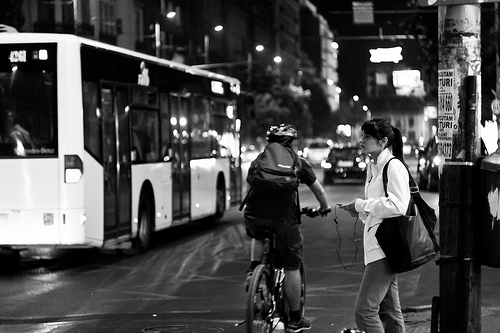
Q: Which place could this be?
A: It is a street.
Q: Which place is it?
A: It is a street.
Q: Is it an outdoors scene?
A: Yes, it is outdoors.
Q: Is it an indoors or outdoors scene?
A: It is outdoors.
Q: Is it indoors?
A: No, it is outdoors.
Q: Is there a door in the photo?
A: Yes, there is a door.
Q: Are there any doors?
A: Yes, there is a door.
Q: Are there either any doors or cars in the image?
A: Yes, there is a door.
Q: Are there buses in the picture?
A: Yes, there is a bus.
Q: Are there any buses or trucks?
A: Yes, there is a bus.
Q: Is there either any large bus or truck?
A: Yes, there is a large bus.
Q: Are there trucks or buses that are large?
A: Yes, the bus is large.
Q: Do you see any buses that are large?
A: Yes, there is a large bus.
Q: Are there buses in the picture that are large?
A: Yes, there is a bus that is large.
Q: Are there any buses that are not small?
A: Yes, there is a large bus.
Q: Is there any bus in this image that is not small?
A: Yes, there is a large bus.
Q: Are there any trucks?
A: No, there are no trucks.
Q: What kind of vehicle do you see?
A: The vehicle is a bus.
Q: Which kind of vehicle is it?
A: The vehicle is a bus.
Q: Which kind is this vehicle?
A: This is a bus.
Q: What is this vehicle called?
A: This is a bus.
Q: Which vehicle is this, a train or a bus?
A: This is a bus.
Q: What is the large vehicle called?
A: The vehicle is a bus.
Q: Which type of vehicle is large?
A: The vehicle is a bus.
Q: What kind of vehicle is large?
A: The vehicle is a bus.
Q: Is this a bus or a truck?
A: This is a bus.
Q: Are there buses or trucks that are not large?
A: No, there is a bus but it is large.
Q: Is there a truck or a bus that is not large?
A: No, there is a bus but it is large.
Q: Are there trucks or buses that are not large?
A: No, there is a bus but it is large.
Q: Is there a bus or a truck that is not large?
A: No, there is a bus but it is large.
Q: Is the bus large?
A: Yes, the bus is large.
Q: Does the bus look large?
A: Yes, the bus is large.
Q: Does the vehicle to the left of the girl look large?
A: Yes, the bus is large.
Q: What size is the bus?
A: The bus is large.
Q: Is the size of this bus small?
A: No, the bus is large.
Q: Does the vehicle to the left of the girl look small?
A: No, the bus is large.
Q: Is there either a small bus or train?
A: No, there is a bus but it is large.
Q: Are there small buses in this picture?
A: No, there is a bus but it is large.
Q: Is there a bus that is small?
A: No, there is a bus but it is large.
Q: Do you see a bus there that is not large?
A: No, there is a bus but it is large.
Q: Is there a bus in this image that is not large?
A: No, there is a bus but it is large.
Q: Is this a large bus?
A: Yes, this is a large bus.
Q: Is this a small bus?
A: No, this is a large bus.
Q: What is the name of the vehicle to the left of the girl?
A: The vehicle is a bus.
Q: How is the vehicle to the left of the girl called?
A: The vehicle is a bus.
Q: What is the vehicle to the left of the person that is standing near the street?
A: The vehicle is a bus.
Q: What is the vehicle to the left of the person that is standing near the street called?
A: The vehicle is a bus.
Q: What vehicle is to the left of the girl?
A: The vehicle is a bus.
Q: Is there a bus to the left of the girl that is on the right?
A: Yes, there is a bus to the left of the girl.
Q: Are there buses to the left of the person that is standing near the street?
A: Yes, there is a bus to the left of the girl.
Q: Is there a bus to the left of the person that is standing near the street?
A: Yes, there is a bus to the left of the girl.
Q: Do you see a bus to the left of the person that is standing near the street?
A: Yes, there is a bus to the left of the girl.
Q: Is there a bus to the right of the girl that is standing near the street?
A: No, the bus is to the left of the girl.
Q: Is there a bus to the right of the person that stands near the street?
A: No, the bus is to the left of the girl.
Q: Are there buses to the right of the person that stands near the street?
A: No, the bus is to the left of the girl.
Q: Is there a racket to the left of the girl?
A: No, there is a bus to the left of the girl.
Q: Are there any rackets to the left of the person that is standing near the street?
A: No, there is a bus to the left of the girl.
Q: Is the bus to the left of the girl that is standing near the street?
A: Yes, the bus is to the left of the girl.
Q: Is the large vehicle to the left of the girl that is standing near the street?
A: Yes, the bus is to the left of the girl.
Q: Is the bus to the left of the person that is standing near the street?
A: Yes, the bus is to the left of the girl.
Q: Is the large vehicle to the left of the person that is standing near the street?
A: Yes, the bus is to the left of the girl.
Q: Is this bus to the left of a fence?
A: No, the bus is to the left of the girl.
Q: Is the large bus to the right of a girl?
A: No, the bus is to the left of a girl.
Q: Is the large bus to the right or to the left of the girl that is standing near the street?
A: The bus is to the left of the girl.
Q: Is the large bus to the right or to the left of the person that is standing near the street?
A: The bus is to the left of the girl.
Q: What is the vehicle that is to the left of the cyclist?
A: The vehicle is a bus.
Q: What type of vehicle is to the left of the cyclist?
A: The vehicle is a bus.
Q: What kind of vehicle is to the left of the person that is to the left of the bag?
A: The vehicle is a bus.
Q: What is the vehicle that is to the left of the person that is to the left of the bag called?
A: The vehicle is a bus.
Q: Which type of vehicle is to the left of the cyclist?
A: The vehicle is a bus.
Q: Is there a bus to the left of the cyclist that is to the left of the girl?
A: Yes, there is a bus to the left of the bicyclist.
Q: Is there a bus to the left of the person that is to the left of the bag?
A: Yes, there is a bus to the left of the bicyclist.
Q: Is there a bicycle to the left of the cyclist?
A: No, there is a bus to the left of the cyclist.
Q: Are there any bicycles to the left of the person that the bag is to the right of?
A: No, there is a bus to the left of the cyclist.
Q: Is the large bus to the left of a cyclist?
A: Yes, the bus is to the left of a cyclist.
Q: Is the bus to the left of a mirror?
A: No, the bus is to the left of a cyclist.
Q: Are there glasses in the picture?
A: No, there are no glasses.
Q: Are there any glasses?
A: No, there are no glasses.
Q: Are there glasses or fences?
A: No, there are no glasses or fences.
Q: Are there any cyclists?
A: Yes, there is a cyclist.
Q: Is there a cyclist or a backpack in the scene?
A: Yes, there is a cyclist.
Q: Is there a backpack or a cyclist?
A: Yes, there is a cyclist.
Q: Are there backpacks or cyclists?
A: Yes, there is a cyclist.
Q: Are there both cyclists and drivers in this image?
A: No, there is a cyclist but no drivers.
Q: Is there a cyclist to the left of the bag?
A: Yes, there is a cyclist to the left of the bag.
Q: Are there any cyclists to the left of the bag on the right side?
A: Yes, there is a cyclist to the left of the bag.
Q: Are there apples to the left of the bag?
A: No, there is a cyclist to the left of the bag.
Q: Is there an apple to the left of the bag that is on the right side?
A: No, there is a cyclist to the left of the bag.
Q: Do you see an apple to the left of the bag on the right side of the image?
A: No, there is a cyclist to the left of the bag.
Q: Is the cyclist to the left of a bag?
A: Yes, the cyclist is to the left of a bag.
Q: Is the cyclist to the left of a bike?
A: No, the cyclist is to the left of a bag.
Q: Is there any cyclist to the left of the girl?
A: Yes, there is a cyclist to the left of the girl.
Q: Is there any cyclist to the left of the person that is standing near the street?
A: Yes, there is a cyclist to the left of the girl.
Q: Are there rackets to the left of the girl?
A: No, there is a cyclist to the left of the girl.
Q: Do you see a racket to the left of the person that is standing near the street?
A: No, there is a cyclist to the left of the girl.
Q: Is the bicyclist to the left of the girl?
A: Yes, the bicyclist is to the left of the girl.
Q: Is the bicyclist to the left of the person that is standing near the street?
A: Yes, the bicyclist is to the left of the girl.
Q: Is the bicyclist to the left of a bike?
A: No, the bicyclist is to the left of the girl.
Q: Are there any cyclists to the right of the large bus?
A: Yes, there is a cyclist to the right of the bus.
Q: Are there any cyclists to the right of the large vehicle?
A: Yes, there is a cyclist to the right of the bus.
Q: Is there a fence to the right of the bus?
A: No, there is a cyclist to the right of the bus.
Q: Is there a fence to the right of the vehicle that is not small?
A: No, there is a cyclist to the right of the bus.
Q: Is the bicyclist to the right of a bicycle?
A: No, the bicyclist is to the right of the bus.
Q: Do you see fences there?
A: No, there are no fences.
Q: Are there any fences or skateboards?
A: No, there are no fences or skateboards.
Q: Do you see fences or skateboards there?
A: No, there are no fences or skateboards.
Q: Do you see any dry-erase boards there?
A: No, there are no dry-erase boards.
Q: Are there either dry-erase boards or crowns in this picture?
A: No, there are no dry-erase boards or crowns.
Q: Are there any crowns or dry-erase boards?
A: No, there are no dry-erase boards or crowns.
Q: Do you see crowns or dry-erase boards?
A: No, there are no dry-erase boards or crowns.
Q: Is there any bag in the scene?
A: Yes, there is a bag.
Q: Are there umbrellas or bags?
A: Yes, there is a bag.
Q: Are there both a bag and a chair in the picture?
A: No, there is a bag but no chairs.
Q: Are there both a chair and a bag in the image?
A: No, there is a bag but no chairs.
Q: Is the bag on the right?
A: Yes, the bag is on the right of the image.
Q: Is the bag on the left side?
A: No, the bag is on the right of the image.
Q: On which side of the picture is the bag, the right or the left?
A: The bag is on the right of the image.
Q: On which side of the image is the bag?
A: The bag is on the right of the image.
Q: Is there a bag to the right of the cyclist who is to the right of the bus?
A: Yes, there is a bag to the right of the cyclist.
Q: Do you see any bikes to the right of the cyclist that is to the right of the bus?
A: No, there is a bag to the right of the cyclist.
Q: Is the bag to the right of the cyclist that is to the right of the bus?
A: Yes, the bag is to the right of the cyclist.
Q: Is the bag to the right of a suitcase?
A: No, the bag is to the right of the cyclist.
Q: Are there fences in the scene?
A: No, there are no fences.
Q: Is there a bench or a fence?
A: No, there are no fences or benches.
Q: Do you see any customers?
A: No, there are no customers.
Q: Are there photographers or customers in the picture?
A: No, there are no customers or photographers.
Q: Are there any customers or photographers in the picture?
A: No, there are no customers or photographers.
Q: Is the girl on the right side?
A: Yes, the girl is on the right of the image.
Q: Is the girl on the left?
A: No, the girl is on the right of the image.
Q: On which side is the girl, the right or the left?
A: The girl is on the right of the image.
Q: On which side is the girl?
A: The girl is on the right of the image.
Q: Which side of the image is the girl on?
A: The girl is on the right of the image.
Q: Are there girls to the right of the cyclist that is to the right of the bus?
A: Yes, there is a girl to the right of the cyclist.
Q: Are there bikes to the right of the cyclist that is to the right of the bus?
A: No, there is a girl to the right of the cyclist.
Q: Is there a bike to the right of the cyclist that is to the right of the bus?
A: No, there is a girl to the right of the cyclist.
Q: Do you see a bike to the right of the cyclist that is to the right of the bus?
A: No, there is a girl to the right of the cyclist.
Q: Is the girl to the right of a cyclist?
A: Yes, the girl is to the right of a cyclist.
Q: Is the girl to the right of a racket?
A: No, the girl is to the right of a cyclist.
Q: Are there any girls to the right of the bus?
A: Yes, there is a girl to the right of the bus.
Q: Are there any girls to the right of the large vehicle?
A: Yes, there is a girl to the right of the bus.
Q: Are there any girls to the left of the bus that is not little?
A: No, the girl is to the right of the bus.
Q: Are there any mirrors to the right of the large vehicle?
A: No, there is a girl to the right of the bus.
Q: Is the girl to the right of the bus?
A: Yes, the girl is to the right of the bus.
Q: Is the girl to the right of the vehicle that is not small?
A: Yes, the girl is to the right of the bus.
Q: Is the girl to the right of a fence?
A: No, the girl is to the right of the bus.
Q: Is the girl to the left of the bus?
A: No, the girl is to the right of the bus.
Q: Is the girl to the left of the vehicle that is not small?
A: No, the girl is to the right of the bus.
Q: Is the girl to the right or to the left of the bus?
A: The girl is to the right of the bus.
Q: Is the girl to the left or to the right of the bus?
A: The girl is to the right of the bus.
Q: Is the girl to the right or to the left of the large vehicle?
A: The girl is to the right of the bus.